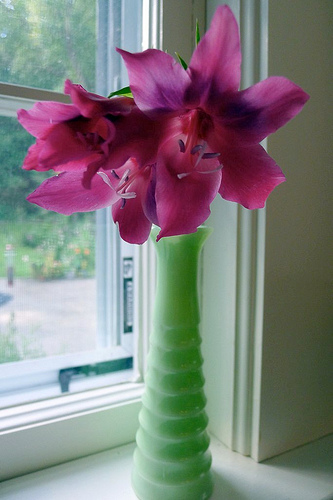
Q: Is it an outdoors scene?
A: Yes, it is outdoors.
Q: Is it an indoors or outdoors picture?
A: It is outdoors.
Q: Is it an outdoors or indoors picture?
A: It is outdoors.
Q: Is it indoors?
A: No, it is outdoors.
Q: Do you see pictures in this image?
A: No, there are no pictures.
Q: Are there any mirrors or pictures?
A: No, there are no pictures or mirrors.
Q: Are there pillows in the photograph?
A: No, there are no pillows.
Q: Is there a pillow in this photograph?
A: No, there are no pillows.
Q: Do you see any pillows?
A: No, there are no pillows.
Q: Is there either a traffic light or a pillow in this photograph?
A: No, there are no pillows or traffic lights.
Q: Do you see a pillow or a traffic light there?
A: No, there are no pillows or traffic lights.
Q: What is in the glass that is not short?
A: The flower is in the glass.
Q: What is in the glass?
A: The flower is in the glass.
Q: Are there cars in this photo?
A: No, there are no cars.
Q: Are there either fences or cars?
A: No, there are no cars or fences.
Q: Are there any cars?
A: No, there are no cars.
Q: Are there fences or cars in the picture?
A: No, there are no cars or fences.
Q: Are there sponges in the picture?
A: No, there are no sponges.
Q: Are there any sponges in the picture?
A: No, there are no sponges.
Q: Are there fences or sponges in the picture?
A: No, there are no sponges or fences.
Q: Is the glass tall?
A: Yes, the glass is tall.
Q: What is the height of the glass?
A: The glass is tall.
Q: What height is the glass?
A: The glass is tall.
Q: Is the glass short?
A: No, the glass is tall.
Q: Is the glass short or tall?
A: The glass is tall.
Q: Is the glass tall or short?
A: The glass is tall.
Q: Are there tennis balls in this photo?
A: No, there are no tennis balls.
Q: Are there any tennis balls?
A: No, there are no tennis balls.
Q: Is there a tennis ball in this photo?
A: No, there are no tennis balls.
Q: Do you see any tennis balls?
A: No, there are no tennis balls.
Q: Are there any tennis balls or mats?
A: No, there are no tennis balls or mats.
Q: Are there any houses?
A: No, there are no houses.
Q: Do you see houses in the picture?
A: No, there are no houses.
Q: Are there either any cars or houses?
A: No, there are no houses or cars.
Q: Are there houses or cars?
A: No, there are no houses or cars.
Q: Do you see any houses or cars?
A: No, there are no houses or cars.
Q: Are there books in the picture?
A: No, there are no books.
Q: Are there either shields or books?
A: No, there are no books or shields.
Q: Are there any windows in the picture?
A: Yes, there is a window.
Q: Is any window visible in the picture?
A: Yes, there is a window.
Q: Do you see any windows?
A: Yes, there is a window.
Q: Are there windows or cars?
A: Yes, there is a window.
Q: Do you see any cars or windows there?
A: Yes, there is a window.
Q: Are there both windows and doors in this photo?
A: No, there is a window but no doors.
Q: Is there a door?
A: No, there are no doors.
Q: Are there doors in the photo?
A: No, there are no doors.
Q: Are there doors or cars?
A: No, there are no doors or cars.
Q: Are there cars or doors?
A: No, there are no doors or cars.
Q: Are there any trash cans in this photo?
A: No, there are no trash cans.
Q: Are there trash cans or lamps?
A: No, there are no trash cans or lamps.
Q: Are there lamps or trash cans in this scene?
A: No, there are no trash cans or lamps.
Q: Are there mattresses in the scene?
A: No, there are no mattresses.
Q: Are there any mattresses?
A: No, there are no mattresses.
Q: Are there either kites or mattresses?
A: No, there are no mattresses or kites.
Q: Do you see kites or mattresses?
A: No, there are no mattresses or kites.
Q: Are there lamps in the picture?
A: No, there are no lamps.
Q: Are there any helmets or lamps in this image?
A: No, there are no lamps or helmets.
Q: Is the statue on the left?
A: Yes, the statue is on the left of the image.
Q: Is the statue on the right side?
A: No, the statue is on the left of the image.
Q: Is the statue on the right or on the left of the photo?
A: The statue is on the left of the image.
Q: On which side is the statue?
A: The statue is on the left of the image.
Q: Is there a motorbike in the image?
A: No, there are no motorcycles.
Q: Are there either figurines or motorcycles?
A: No, there are no motorcycles or figurines.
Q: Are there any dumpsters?
A: No, there are no dumpsters.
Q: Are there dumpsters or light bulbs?
A: No, there are no dumpsters or light bulbs.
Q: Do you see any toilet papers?
A: No, there are no toilet papers.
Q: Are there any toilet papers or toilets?
A: No, there are no toilet papers or toilets.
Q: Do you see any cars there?
A: No, there are no cars.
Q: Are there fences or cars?
A: No, there are no cars or fences.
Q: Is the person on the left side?
A: Yes, the person is on the left of the image.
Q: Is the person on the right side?
A: No, the person is on the left of the image.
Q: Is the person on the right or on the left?
A: The person is on the left of the image.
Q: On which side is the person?
A: The person is on the left of the image.